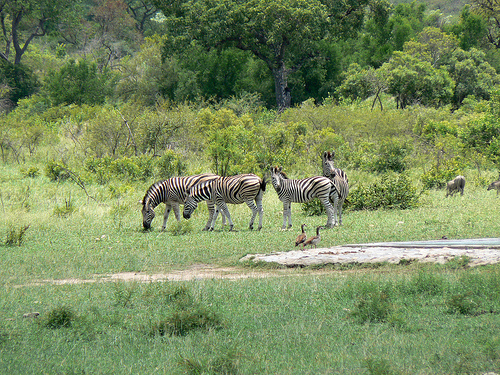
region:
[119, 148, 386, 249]
a group of four zebras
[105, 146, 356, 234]
four zebras standing in the grass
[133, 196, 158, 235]
head touching the ground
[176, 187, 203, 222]
head angled down towards the ground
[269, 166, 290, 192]
head turned to the side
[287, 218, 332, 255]
two birds in the grass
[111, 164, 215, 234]
zebra grazing in the grass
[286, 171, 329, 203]
black and white stripes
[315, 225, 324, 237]
black neck on the bird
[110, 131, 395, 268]
animals on the grass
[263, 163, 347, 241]
zebra looking at camera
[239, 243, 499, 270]
mound of sand beside grass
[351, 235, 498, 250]
patch of pavement beside grass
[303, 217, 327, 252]
duck walking in grass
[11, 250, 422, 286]
patch of dirt in grass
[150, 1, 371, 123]
large tree in the middle of brush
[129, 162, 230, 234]
zebra grazing in grass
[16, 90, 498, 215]
overgrown brush behind zebras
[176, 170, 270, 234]
second zebra grazing in grass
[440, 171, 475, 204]
animal grazing in grass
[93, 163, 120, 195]
small short green tree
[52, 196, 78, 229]
small short green tree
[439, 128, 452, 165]
small short green tree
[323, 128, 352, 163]
small short green tree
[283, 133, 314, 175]
small short green tree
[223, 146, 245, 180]
small short green tree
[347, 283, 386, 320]
small short green tree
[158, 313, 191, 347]
small short green tree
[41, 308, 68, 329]
small short green tree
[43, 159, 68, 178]
small short green tree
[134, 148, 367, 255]
Zebra are standing in grass.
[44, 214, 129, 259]
Grass is green color.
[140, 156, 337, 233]
Zebra is black and white color.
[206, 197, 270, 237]
Four legs for zebra.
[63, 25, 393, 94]
Trees are green color.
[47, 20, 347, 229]
trees are behind the zebra.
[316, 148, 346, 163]
Two pointed ears for zebra.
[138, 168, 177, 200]
Short hairs on back of zebra.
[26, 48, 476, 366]
Day time picture.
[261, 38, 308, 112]
Woods are grey color.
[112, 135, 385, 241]
group of four zebras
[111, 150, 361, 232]
zebras standing on the grass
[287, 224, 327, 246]
two birds on the grass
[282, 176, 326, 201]
black and whtie stripes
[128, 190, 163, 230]
head on the ground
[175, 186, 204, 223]
head bent down towards the ground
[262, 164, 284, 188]
head tilted to the side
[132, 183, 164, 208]
hair along the neck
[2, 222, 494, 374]
field of green grass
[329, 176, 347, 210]
black hair on the bottom of the tail